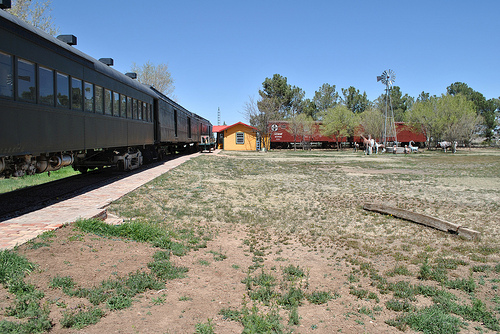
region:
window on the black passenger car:
[15, 55, 36, 104]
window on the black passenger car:
[35, 65, 54, 103]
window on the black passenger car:
[53, 68, 67, 107]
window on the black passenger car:
[81, 80, 96, 116]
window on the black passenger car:
[102, 86, 113, 116]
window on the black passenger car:
[122, 95, 134, 120]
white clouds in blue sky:
[168, 14, 228, 41]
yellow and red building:
[220, 116, 258, 165]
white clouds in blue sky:
[413, 11, 459, 41]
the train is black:
[12, 20, 234, 165]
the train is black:
[17, 23, 207, 164]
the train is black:
[15, 28, 200, 168]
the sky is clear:
[149, 39, 355, 76]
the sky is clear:
[178, 18, 326, 71]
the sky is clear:
[163, 14, 345, 65]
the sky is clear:
[152, 30, 314, 65]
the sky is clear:
[144, 18, 342, 76]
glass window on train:
[0, 50, 15, 97]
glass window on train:
[16, 59, 37, 101]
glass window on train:
[38, 63, 56, 108]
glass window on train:
[56, 69, 71, 106]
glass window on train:
[72, 76, 82, 108]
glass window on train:
[82, 81, 94, 113]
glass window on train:
[94, 84, 104, 113]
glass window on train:
[103, 86, 113, 112]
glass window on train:
[112, 90, 122, 115]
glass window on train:
[127, 94, 134, 117]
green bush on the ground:
[124, 220, 186, 260]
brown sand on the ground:
[173, 277, 226, 311]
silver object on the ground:
[356, 188, 488, 250]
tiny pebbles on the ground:
[343, 293, 385, 320]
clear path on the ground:
[11, 164, 172, 203]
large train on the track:
[43, 112, 204, 159]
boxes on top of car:
[54, 23, 148, 73]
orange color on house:
[224, 129, 261, 149]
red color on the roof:
[214, 118, 236, 129]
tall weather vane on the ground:
[358, 61, 411, 160]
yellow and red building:
[209, 119, 259, 150]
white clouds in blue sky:
[173, 23, 207, 45]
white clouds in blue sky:
[405, 14, 430, 37]